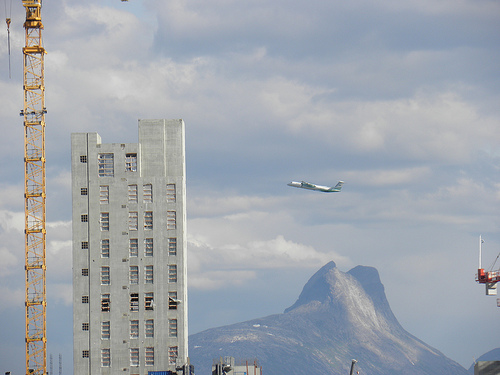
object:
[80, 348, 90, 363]
window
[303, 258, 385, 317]
mountain top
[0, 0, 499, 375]
sky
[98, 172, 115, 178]
window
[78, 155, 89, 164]
window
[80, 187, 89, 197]
window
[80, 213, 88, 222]
window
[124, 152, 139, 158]
window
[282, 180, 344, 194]
airplane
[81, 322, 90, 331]
window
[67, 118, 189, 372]
building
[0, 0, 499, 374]
cloud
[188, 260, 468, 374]
mountain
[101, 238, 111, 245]
window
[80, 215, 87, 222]
window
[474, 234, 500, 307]
crane`s part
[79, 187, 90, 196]
window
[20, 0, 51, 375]
equipment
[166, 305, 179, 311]
window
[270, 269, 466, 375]
slope